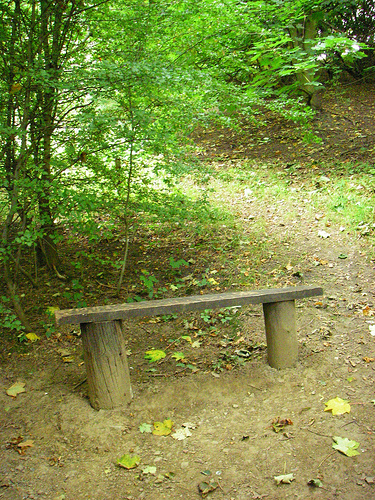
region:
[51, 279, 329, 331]
the seat of a bench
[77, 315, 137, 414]
a brown wooden post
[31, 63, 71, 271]
a brown tree trunk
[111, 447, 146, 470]
a green leaf on the ground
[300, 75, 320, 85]
a green leaf on the tree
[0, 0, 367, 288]
a green leafy tree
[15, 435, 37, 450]
an orange leaf on the ground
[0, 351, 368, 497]
brown dirt on the ground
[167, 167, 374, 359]
a brown dirt path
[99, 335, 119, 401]
cracks in the wood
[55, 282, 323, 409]
an old fashion wooden bench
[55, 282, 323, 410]
a bench created with two logs and a plank of wood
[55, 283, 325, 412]
a wood bench in front of a tree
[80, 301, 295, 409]
two logs holding the plank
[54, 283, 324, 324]
a wood plank on top of two logs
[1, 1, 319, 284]
green leaf trees behind the bench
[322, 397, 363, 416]
a yellow leaf on the ground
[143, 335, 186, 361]
green and yellow leaves under the bench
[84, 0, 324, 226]
green leaves on the tree branches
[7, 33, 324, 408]
a wood bench in front of trees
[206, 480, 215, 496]
the leaves are dry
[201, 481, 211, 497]
the leaves are dry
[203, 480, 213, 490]
the leaves are dry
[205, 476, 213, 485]
the leaves are dry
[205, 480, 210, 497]
the leaves are dry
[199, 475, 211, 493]
the leaves are dry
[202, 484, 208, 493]
the leaves are dry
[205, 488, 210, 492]
the leaves are dry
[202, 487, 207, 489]
the leaves are dry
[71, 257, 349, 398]
bench is brown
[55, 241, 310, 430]
bench is wooden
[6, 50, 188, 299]
green trees behind bench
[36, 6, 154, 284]
trees have thin branches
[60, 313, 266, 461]
dead leaves strewn on ground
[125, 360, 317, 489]
ground is brown and dry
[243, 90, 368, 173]
dirt behind bench is brown and moist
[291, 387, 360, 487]
leaves are yellow and green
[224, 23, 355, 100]
green leaves on branches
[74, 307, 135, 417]
bench has circular base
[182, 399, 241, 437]
brown dirt on the ground of a forest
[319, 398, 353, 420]
a yellow fallen leaf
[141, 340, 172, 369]
a large green fallen leaf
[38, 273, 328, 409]
a three piece wooden bench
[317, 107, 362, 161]
a shadowed area of brush and dirt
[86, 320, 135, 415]
a log bench leg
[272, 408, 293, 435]
a crumpled brown dead leaf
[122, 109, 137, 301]
a loose fallen stick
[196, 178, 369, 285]
a dirt and grass path beaten by hikers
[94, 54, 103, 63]
a small red bird in the tree branches